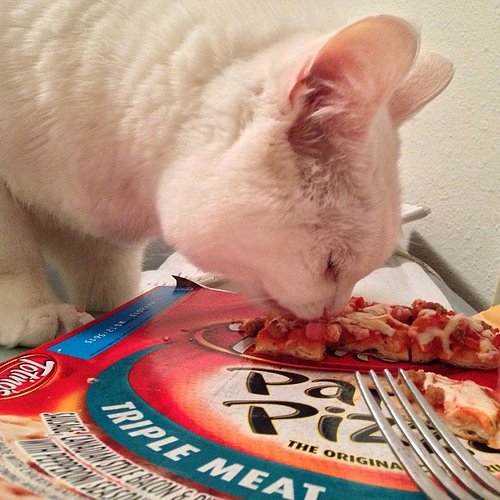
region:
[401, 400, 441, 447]
part of a forkk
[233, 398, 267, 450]
part of a letter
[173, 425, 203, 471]
part of a letter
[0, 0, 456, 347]
white cat on table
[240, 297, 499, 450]
triple meat pizza on box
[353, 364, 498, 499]
silver metal dinner fork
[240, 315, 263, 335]
sausage piece on box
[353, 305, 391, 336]
melted cheese on pizza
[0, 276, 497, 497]
cardboard pizza box on table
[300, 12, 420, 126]
white ear on cat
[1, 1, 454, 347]
white cat eating pizza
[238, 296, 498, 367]
pizza slice on box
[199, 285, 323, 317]
white wiskers on cat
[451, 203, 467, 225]
this is the wall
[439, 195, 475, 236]
the wall is clean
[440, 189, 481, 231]
the wall is white in color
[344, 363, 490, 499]
this is a fork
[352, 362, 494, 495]
the fork is metallic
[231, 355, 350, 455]
these are some writings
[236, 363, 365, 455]
the writings are in black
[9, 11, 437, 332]
this is a cat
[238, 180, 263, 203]
the fur is white in color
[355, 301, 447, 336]
this is some meat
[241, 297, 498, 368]
slice of Totino's pizza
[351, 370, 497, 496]
silver fork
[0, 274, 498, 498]
Totino's Triple Meat Party Pizza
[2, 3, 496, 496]
white cat enjoying slice of Totino's Party Pizza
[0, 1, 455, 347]
white adult cat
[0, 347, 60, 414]
Totino's logo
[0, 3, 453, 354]
white cat eating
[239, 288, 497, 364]
Totino's Triple Meat Party Pizza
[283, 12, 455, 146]
pink cat's ears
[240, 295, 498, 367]
Totino's Party Pizza slice with sausage, Canadian bacon, and and pepperoni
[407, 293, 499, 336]
meatballs on pizza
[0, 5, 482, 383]
a cat eating pizza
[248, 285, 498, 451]
pizza on a box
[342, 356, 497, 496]
a silver fork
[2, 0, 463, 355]
the cat is color white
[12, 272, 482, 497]
a box of pizza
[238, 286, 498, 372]
a slice of pizza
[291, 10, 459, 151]
ears of cat are big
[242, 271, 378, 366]
a mouth on pizza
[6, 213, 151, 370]
front legs of cat